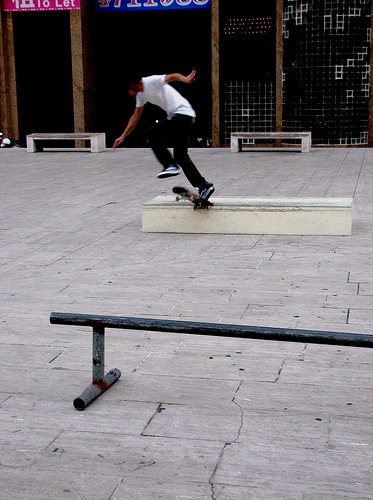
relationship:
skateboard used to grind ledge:
[169, 186, 215, 213] [141, 192, 351, 237]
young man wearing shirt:
[106, 65, 216, 204] [130, 73, 197, 120]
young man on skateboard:
[106, 65, 216, 204] [169, 186, 215, 213]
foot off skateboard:
[154, 164, 181, 180] [169, 186, 215, 213]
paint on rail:
[82, 316, 109, 393] [49, 308, 372, 412]